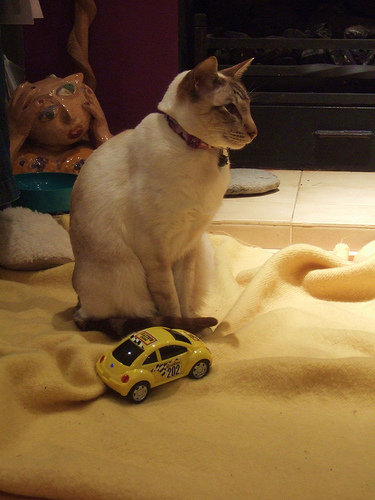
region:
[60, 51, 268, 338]
Cat sitting down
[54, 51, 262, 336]
Cat is sitting down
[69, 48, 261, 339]
White cat sitting down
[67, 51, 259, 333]
White cat is sitting down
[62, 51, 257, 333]
Cat on a blanket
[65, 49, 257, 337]
Cat is on a blanket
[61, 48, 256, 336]
White cat on a blanket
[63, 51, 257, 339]
White cat is on a blanket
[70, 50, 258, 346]
Cat on a yellow blanket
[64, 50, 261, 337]
Cat is on a yellow blanket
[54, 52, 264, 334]
cute tan siamese cat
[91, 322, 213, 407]
little yellow racing beetle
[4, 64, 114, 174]
bizzare piccaso-esque statue of a female face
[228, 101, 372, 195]
black painted wooden drawer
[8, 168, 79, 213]
shiny plastic teal bowl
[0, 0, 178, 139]
burgundy painted wall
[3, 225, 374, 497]
manilla coloured wrinkled blanket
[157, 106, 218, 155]
small purple cat collar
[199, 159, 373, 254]
white floor tiled area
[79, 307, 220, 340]
brown striped cat tail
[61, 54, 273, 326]
cat on the surface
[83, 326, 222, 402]
toy vehicle near cat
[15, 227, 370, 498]
cushion cat rests on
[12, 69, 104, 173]
ceramic figure in back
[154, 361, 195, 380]
graphic and numbering on vehicle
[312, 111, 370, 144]
handle on structure behind cat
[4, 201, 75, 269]
cushion behind the cat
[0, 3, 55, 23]
paper near wall behind cat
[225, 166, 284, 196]
stone on surface behind cat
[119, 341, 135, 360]
window on toy vehicle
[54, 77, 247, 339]
a cat on a bed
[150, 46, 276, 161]
the cat is staring at something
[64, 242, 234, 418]
a yellow car on the bed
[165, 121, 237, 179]
the cat has on a pendant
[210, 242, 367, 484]
a cream colored bed spread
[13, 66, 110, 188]
a strange vase near the bed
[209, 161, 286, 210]
a stone piece on a table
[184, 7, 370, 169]
a green drawer in the background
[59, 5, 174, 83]
a purple wall in the bedroom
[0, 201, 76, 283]
a white fluffy pillow